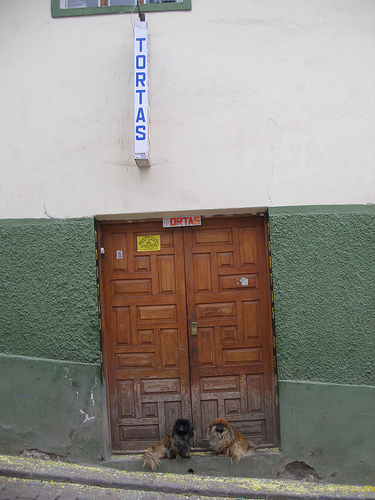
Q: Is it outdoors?
A: Yes, it is outdoors.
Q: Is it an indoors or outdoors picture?
A: It is outdoors.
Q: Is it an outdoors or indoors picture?
A: It is outdoors.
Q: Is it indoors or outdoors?
A: It is outdoors.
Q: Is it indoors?
A: No, it is outdoors.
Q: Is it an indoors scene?
A: No, it is outdoors.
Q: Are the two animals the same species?
A: Yes, all the animals are dogs.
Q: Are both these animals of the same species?
A: Yes, all the animals are dogs.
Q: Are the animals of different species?
A: No, all the animals are dogs.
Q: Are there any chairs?
A: No, there are no chairs.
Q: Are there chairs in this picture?
A: No, there are no chairs.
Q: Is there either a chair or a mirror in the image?
A: No, there are no chairs or mirrors.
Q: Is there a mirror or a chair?
A: No, there are no chairs or mirrors.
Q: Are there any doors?
A: Yes, there is a door.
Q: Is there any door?
A: Yes, there is a door.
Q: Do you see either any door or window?
A: Yes, there is a door.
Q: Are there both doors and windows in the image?
A: Yes, there are both a door and a window.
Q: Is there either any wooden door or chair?
A: Yes, there is a wood door.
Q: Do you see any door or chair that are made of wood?
A: Yes, the door is made of wood.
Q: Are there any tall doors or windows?
A: Yes, there is a tall door.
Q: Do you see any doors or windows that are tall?
A: Yes, the door is tall.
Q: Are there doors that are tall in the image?
A: Yes, there is a tall door.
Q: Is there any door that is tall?
A: Yes, there is a door that is tall.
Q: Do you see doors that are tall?
A: Yes, there is a door that is tall.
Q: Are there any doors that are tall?
A: Yes, there is a door that is tall.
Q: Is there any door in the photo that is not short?
A: Yes, there is a tall door.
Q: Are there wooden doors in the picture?
A: Yes, there is a wood door.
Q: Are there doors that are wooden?
A: Yes, there is a door that is wooden.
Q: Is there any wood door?
A: Yes, there is a door that is made of wood.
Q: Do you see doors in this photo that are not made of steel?
A: Yes, there is a door that is made of wood.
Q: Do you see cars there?
A: No, there are no cars.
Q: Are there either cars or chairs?
A: No, there are no cars or chairs.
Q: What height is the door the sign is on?
A: The door is tall.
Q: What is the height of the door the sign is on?
A: The door is tall.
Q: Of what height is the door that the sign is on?
A: The door is tall.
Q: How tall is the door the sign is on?
A: The door is tall.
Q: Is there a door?
A: Yes, there is a door.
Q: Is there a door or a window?
A: Yes, there is a door.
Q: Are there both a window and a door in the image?
A: Yes, there are both a door and a window.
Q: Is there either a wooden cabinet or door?
A: Yes, there is a wood door.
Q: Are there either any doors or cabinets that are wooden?
A: Yes, the door is wooden.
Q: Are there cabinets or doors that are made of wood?
A: Yes, the door is made of wood.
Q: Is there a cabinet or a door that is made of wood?
A: Yes, the door is made of wood.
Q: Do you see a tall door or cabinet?
A: Yes, there is a tall door.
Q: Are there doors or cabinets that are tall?
A: Yes, the door is tall.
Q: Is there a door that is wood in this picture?
A: Yes, there is a wood door.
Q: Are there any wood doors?
A: Yes, there is a wood door.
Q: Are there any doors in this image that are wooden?
A: Yes, there is a door that is wooden.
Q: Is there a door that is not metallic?
A: Yes, there is a wooden door.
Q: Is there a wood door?
A: Yes, there is a door that is made of wood.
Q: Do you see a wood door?
A: Yes, there is a door that is made of wood.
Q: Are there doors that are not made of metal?
A: Yes, there is a door that is made of wood.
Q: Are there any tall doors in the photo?
A: Yes, there is a tall door.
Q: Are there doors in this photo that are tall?
A: Yes, there is a door that is tall.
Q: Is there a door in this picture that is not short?
A: Yes, there is a tall door.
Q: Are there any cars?
A: No, there are no cars.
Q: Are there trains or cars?
A: No, there are no cars or trains.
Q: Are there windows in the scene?
A: Yes, there is a window.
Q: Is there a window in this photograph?
A: Yes, there is a window.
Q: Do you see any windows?
A: Yes, there is a window.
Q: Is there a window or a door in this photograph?
A: Yes, there is a window.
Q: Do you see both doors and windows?
A: Yes, there are both a window and a door.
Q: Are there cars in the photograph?
A: No, there are no cars.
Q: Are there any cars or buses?
A: No, there are no cars or buses.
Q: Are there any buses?
A: No, there are no buses.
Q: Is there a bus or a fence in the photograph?
A: No, there are no buses or fences.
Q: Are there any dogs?
A: Yes, there is a dog.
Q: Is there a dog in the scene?
A: Yes, there is a dog.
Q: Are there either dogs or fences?
A: Yes, there is a dog.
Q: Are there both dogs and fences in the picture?
A: No, there is a dog but no fences.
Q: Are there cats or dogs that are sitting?
A: Yes, the dog is sitting.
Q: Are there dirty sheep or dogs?
A: Yes, there is a dirty dog.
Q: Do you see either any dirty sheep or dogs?
A: Yes, there is a dirty dog.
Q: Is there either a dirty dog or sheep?
A: Yes, there is a dirty dog.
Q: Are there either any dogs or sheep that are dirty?
A: Yes, the dog is dirty.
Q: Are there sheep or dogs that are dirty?
A: Yes, the dog is dirty.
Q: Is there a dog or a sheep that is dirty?
A: Yes, the dog is dirty.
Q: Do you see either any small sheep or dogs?
A: Yes, there is a small dog.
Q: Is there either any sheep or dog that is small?
A: Yes, the dog is small.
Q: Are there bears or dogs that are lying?
A: Yes, the dog is lying.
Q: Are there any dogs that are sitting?
A: Yes, there is a dog that is sitting.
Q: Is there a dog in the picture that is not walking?
A: Yes, there is a dog that is sitting.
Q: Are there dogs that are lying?
A: Yes, there is a dog that is lying.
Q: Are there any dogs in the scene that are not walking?
A: Yes, there is a dog that is lying.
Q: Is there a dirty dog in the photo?
A: Yes, there is a dirty dog.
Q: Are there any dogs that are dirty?
A: Yes, there is a dog that is dirty.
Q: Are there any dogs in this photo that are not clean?
A: Yes, there is a dirty dog.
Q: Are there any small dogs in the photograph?
A: Yes, there is a small dog.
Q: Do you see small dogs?
A: Yes, there is a small dog.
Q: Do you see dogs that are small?
A: Yes, there is a dog that is small.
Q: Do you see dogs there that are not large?
A: Yes, there is a small dog.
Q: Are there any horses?
A: No, there are no horses.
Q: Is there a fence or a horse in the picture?
A: No, there are no horses or fences.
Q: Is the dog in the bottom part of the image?
A: Yes, the dog is in the bottom of the image.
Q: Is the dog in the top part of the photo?
A: No, the dog is in the bottom of the image.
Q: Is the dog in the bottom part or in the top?
A: The dog is in the bottom of the image.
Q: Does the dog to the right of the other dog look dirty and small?
A: Yes, the dog is dirty and small.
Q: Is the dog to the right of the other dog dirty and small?
A: Yes, the dog is dirty and small.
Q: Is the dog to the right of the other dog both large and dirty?
A: No, the dog is dirty but small.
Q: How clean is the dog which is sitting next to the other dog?
A: The dog is dirty.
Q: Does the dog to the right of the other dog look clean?
A: No, the dog is dirty.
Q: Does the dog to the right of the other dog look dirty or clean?
A: The dog is dirty.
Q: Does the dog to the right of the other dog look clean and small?
A: No, the dog is small but dirty.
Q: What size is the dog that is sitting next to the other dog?
A: The dog is small.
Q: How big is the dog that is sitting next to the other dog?
A: The dog is small.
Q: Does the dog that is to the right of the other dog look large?
A: No, the dog is small.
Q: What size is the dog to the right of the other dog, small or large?
A: The dog is small.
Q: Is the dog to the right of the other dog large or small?
A: The dog is small.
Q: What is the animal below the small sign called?
A: The animal is a dog.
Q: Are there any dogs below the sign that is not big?
A: Yes, there is a dog below the sign.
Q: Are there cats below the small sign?
A: No, there is a dog below the sign.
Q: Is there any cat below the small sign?
A: No, there is a dog below the sign.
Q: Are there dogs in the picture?
A: Yes, there is a dog.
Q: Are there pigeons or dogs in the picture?
A: Yes, there is a dog.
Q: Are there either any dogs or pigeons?
A: Yes, there is a dog.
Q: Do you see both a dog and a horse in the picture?
A: No, there is a dog but no horses.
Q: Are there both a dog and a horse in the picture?
A: No, there is a dog but no horses.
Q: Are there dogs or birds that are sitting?
A: Yes, the dog is sitting.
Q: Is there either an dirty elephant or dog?
A: Yes, there is a dirty dog.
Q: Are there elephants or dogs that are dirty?
A: Yes, the dog is dirty.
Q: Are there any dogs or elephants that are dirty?
A: Yes, the dog is dirty.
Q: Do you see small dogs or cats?
A: Yes, there is a small dog.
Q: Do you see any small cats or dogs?
A: Yes, there is a small dog.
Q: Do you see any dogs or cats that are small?
A: Yes, the dog is small.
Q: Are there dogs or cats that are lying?
A: Yes, the dog is lying.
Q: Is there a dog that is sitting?
A: Yes, there is a dog that is sitting.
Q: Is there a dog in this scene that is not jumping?
A: Yes, there is a dog that is sitting.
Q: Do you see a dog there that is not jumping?
A: Yes, there is a dog that is sitting .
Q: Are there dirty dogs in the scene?
A: Yes, there is a dirty dog.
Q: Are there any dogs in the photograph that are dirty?
A: Yes, there is a dog that is dirty.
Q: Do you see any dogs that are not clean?
A: Yes, there is a dirty dog.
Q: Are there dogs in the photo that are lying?
A: Yes, there is a dog that is lying.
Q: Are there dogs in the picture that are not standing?
A: Yes, there is a dog that is lying.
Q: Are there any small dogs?
A: Yes, there is a small dog.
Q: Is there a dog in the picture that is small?
A: Yes, there is a dog that is small.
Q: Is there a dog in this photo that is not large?
A: Yes, there is a small dog.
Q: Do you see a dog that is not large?
A: Yes, there is a small dog.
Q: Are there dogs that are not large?
A: Yes, there is a small dog.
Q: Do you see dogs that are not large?
A: Yes, there is a small dog.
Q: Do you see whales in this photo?
A: No, there are no whales.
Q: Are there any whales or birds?
A: No, there are no whales or birds.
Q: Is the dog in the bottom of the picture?
A: Yes, the dog is in the bottom of the image.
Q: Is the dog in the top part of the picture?
A: No, the dog is in the bottom of the image.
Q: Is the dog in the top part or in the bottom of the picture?
A: The dog is in the bottom of the image.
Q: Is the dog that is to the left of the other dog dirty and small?
A: Yes, the dog is dirty and small.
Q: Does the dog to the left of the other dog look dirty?
A: Yes, the dog is dirty.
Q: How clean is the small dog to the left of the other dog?
A: The dog is dirty.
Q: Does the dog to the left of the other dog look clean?
A: No, the dog is dirty.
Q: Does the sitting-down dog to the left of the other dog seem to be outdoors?
A: Yes, the dog is outdoors.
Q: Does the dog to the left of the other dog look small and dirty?
A: Yes, the dog is small and dirty.